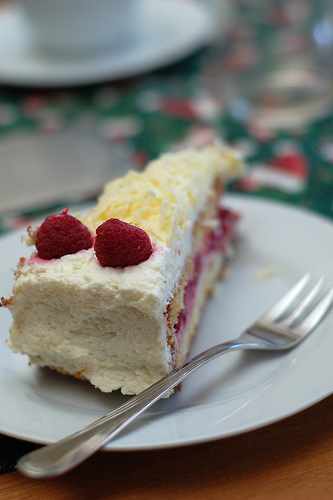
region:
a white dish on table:
[0, 146, 329, 461]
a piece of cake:
[5, 119, 251, 411]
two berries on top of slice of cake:
[5, 115, 259, 412]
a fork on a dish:
[15, 266, 331, 484]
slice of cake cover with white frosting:
[14, 133, 252, 404]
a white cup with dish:
[3, 2, 230, 90]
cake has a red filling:
[14, 135, 261, 406]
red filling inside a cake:
[160, 200, 244, 366]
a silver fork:
[13, 259, 331, 497]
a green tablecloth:
[0, 0, 327, 223]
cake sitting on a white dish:
[6, 135, 251, 411]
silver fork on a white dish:
[0, 266, 332, 487]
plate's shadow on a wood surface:
[4, 395, 330, 490]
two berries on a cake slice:
[28, 205, 156, 274]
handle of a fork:
[7, 336, 236, 485]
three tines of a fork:
[255, 267, 332, 365]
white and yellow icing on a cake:
[14, 136, 228, 304]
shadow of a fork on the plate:
[104, 343, 266, 434]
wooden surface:
[0, 388, 326, 498]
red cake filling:
[162, 198, 240, 358]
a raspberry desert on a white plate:
[5, 134, 226, 364]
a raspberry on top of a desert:
[28, 209, 93, 261]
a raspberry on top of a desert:
[93, 215, 154, 275]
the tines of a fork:
[277, 265, 332, 339]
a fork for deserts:
[10, 272, 331, 481]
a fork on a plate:
[211, 279, 329, 406]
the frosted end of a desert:
[6, 272, 174, 405]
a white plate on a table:
[176, 395, 302, 480]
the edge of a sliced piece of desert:
[181, 173, 244, 299]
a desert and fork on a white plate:
[7, 138, 323, 487]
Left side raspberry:
[35, 212, 92, 260]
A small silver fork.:
[15, 272, 331, 476]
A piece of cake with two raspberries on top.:
[11, 142, 239, 397]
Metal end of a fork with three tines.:
[255, 273, 332, 351]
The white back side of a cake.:
[8, 272, 174, 395]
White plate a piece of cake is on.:
[0, 193, 331, 450]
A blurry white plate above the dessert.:
[0, 0, 220, 84]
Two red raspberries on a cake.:
[36, 213, 153, 271]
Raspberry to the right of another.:
[94, 216, 151, 267]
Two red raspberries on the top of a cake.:
[34, 208, 151, 266]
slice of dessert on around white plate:
[14, 186, 324, 452]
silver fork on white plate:
[12, 265, 316, 480]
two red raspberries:
[29, 207, 150, 265]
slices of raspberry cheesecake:
[23, 147, 225, 380]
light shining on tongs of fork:
[259, 266, 331, 334]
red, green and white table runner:
[126, 81, 205, 130]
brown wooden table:
[172, 455, 318, 494]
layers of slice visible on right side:
[146, 149, 247, 383]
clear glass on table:
[212, 7, 331, 127]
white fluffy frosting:
[38, 281, 140, 349]